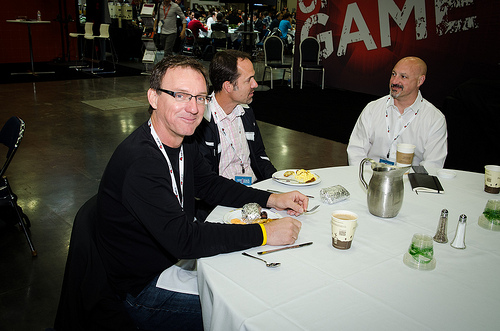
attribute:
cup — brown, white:
[333, 214, 358, 253]